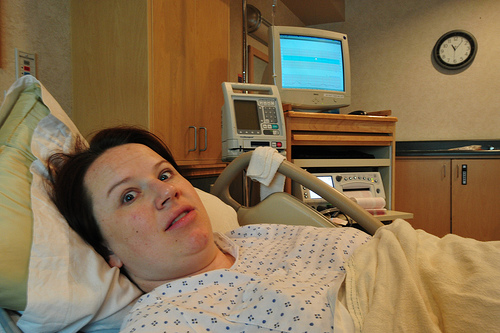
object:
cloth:
[246, 144, 286, 202]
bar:
[210, 149, 385, 235]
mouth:
[162, 203, 195, 232]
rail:
[240, 0, 273, 92]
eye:
[122, 187, 139, 206]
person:
[42, 123, 498, 333]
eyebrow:
[106, 175, 134, 198]